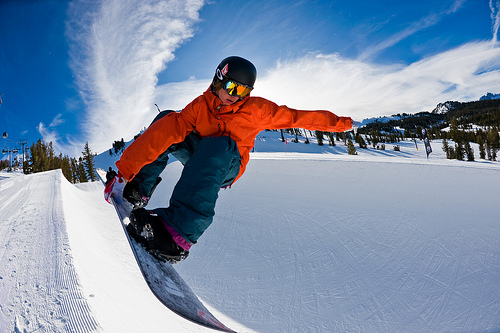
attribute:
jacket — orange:
[102, 86, 352, 210]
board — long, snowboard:
[92, 173, 196, 331]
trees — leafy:
[24, 139, 97, 184]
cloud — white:
[69, 8, 159, 128]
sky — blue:
[270, 9, 477, 44]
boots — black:
[122, 203, 189, 285]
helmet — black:
[209, 55, 259, 92]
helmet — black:
[203, 52, 262, 106]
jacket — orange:
[114, 89, 353, 188]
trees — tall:
[26, 136, 96, 182]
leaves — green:
[453, 142, 474, 159]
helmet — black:
[202, 49, 271, 89]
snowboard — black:
[96, 164, 237, 331]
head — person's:
[205, 51, 261, 113]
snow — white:
[3, 144, 484, 316]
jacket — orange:
[112, 80, 354, 199]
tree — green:
[45, 138, 57, 170]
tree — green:
[80, 141, 96, 177]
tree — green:
[68, 156, 79, 184]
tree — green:
[32, 138, 46, 169]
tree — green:
[68, 156, 76, 184]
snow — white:
[2, 132, 495, 331]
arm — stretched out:
[264, 100, 366, 135]